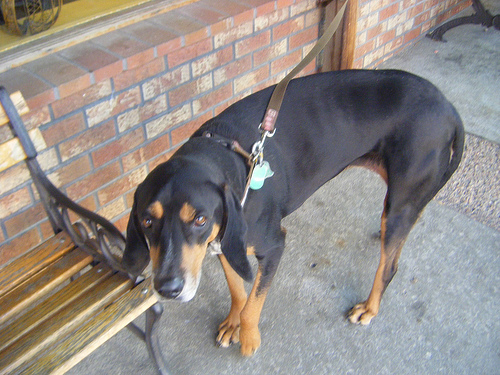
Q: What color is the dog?
A: Black and brown.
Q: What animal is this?
A: Dog.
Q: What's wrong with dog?
A: Scared.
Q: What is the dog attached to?
A: Leash.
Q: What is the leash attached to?
A: Collar.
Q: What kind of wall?
A: Brick.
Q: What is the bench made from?
A: Wood and metal.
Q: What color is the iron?
A: Iron.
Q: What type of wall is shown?
A: Brick.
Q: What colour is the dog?
A: Black and brown.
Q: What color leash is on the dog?
A: Brown.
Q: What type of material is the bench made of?
A: Wood.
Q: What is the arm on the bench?
A: Decorative metal.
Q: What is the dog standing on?
A: Sidewalk.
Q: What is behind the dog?
A: Brick wall.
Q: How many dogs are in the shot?
A: One.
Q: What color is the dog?
A: Black.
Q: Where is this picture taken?
A: The sidewalk.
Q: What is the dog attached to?
A: A leash.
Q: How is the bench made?
A: Of wood.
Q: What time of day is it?
A: Daytime.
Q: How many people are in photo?
A: None.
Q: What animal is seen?
A: A dog.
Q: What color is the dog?
A: Black with brown markings.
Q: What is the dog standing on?
A: A sidewalk.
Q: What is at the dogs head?
A: A bench.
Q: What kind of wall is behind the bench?
A: A brick wall.